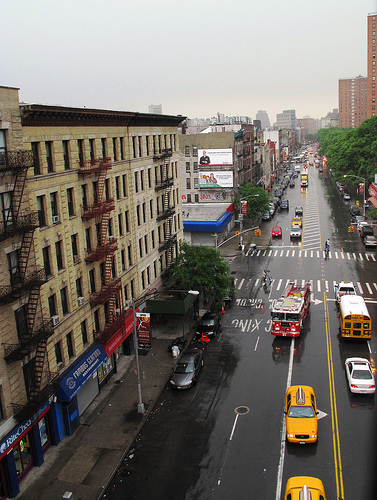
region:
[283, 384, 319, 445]
a yellow cab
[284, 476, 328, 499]
a yellow cab with sign on top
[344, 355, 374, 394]
a white car with sun roof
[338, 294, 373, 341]
a yellow and white school bus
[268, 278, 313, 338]
a red and white fire truck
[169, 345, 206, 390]
a gray car on side of street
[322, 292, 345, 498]
two solid yellow lines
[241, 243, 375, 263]
a cross walk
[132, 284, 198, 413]
a metal surf light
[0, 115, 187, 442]
five story high apartments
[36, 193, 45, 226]
A window in the photo.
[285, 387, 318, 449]
A yellow cab in the photo.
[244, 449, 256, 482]
A road with tarmac in the photo.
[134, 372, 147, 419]
A street light pole.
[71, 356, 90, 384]
A canopy in the picture.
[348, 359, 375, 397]
A white car in the photo.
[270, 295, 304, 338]
A fire truck in the photo.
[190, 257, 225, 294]
A tree in the photo.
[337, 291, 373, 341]
A school bus in the photo.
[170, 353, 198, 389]
A gray car in the photo.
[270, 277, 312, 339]
red fire truck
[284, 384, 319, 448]
yellow taxi cab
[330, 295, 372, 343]
school bus on the street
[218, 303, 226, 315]
orange traffic cone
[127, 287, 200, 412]
street light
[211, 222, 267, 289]
traffic light on red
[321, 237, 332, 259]
person crossing the street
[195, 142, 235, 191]
two billboards with people on them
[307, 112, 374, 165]
row of green bushy trees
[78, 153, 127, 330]
fire escapes on side on building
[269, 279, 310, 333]
this is a fire brigade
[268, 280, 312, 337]
the brigade is red in color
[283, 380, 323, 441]
this is a taxi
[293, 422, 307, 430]
the taxi is yellow in color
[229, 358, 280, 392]
this is a road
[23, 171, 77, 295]
this is a building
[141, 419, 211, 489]
the road is wet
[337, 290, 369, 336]
this is a bus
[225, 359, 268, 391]
the road is tarmacked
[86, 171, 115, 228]
these are the staircase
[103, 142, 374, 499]
a long wet city street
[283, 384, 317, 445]
a yellow taxi cab behind another one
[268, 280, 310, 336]
red fire engine to the left of a school bus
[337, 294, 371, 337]
a yellow school bus to right of the fire engine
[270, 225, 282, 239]
red car at the intersection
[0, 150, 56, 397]
black fire escapes on the left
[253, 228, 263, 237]
red traffic light to the left of the red car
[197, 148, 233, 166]
top billboard with man in black on it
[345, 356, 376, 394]
white car behind the school bus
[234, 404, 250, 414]
manhole to the left of the yellow cab